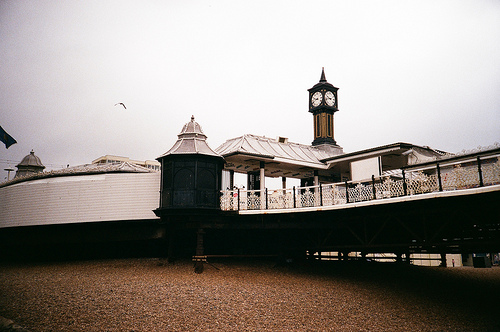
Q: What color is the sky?
A: Grey.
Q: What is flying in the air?
A: Bird.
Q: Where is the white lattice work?
A: On the walkway.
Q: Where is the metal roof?
A: Mid center with white poles under.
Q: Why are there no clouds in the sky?
A: Clear day.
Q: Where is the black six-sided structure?
A: Beside the white wall.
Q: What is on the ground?
A: Brown sand and gravel.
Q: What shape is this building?
A: Circular.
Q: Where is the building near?
A: A beach.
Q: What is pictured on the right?
A: Boardwalk.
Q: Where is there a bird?
A: In sky.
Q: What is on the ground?
A: Sand.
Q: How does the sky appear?
A: Cloudy.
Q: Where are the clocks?
A: On tower.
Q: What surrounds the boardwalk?
A: White fence.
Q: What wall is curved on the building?
A: Left side wall.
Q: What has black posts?
A: The fence.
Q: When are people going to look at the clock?
A: When they need to know the time.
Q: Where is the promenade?
A: In front of the clock.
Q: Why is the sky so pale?
A: It's overcast.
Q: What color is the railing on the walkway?
A: Black and white.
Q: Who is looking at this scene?
A: The photographer.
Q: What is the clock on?
A: A tower.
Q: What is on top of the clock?
A: A small spire.